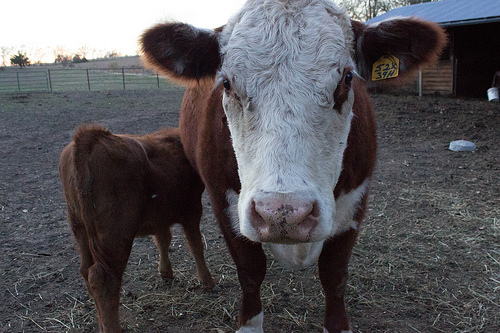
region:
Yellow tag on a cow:
[371, 62, 402, 80]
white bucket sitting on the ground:
[485, 85, 498, 104]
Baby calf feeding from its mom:
[58, 125, 225, 327]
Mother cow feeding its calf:
[140, 1, 447, 328]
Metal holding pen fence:
[48, 69, 180, 95]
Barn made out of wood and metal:
[362, 4, 499, 96]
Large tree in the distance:
[12, 55, 27, 68]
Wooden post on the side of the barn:
[417, 67, 426, 95]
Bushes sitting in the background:
[53, 52, 87, 65]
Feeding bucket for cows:
[486, 87, 498, 106]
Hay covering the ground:
[380, 226, 478, 300]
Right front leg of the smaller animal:
[181, 223, 227, 298]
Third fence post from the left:
[79, 63, 100, 94]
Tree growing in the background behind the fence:
[5, 51, 39, 75]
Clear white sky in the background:
[27, 16, 136, 40]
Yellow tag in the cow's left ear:
[369, 53, 402, 84]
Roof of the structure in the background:
[420, 3, 497, 23]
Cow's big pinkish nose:
[245, 186, 316, 245]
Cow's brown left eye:
[328, 56, 358, 120]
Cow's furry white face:
[252, 20, 319, 180]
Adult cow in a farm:
[140, 1, 450, 331]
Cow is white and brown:
[133, 1, 445, 332]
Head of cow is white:
[213, 0, 360, 265]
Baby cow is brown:
[41, 115, 223, 332]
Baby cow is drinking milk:
[52, 119, 225, 331]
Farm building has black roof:
[366, 0, 498, 107]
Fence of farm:
[5, 63, 182, 95]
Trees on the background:
[1, 46, 125, 66]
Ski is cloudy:
[3, 0, 223, 49]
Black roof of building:
[366, 4, 498, 27]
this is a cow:
[183, 4, 396, 331]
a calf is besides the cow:
[59, 127, 179, 331]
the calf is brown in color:
[65, 128, 183, 331]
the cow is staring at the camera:
[171, 2, 441, 321]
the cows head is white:
[226, 3, 344, 233]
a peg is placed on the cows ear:
[371, 54, 402, 82]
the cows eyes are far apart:
[216, 65, 356, 96]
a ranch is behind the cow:
[451, 1, 498, 80]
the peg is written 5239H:
[366, 56, 404, 83]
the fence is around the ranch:
[2, 68, 149, 93]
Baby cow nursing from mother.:
[58, 106, 271, 321]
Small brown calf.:
[51, 113, 231, 326]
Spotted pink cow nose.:
[233, 191, 330, 253]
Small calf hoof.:
[194, 275, 231, 293]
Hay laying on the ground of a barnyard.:
[0, 208, 479, 316]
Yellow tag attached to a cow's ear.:
[361, 51, 418, 89]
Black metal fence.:
[0, 56, 227, 99]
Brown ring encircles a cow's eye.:
[326, 58, 371, 113]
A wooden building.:
[356, 3, 497, 122]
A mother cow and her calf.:
[36, 28, 429, 322]